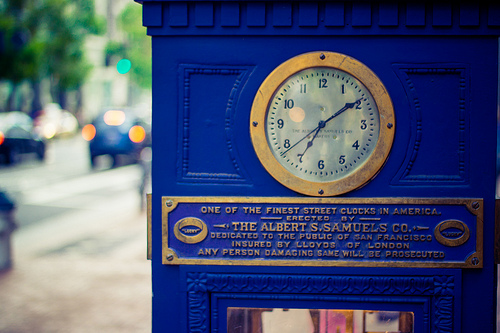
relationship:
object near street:
[148, 4, 495, 331] [3, 132, 150, 332]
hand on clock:
[305, 122, 325, 149] [220, 39, 405, 207]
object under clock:
[135, 0, 500, 333] [245, 49, 398, 197]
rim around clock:
[248, 49, 395, 199] [220, 39, 405, 207]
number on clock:
[339, 79, 348, 97] [245, 49, 398, 197]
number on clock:
[345, 135, 360, 149] [245, 49, 398, 197]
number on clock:
[335, 149, 350, 169] [239, 46, 396, 217]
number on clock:
[314, 158, 326, 170] [245, 49, 398, 197]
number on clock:
[296, 152, 306, 162] [245, 49, 398, 197]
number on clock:
[273, 114, 287, 135] [243, 35, 407, 201]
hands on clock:
[272, 95, 360, 161] [245, 49, 398, 197]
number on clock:
[314, 75, 331, 90] [245, 49, 398, 197]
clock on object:
[131, 1, 498, 331] [135, 0, 500, 333]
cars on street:
[3, 103, 159, 270] [3, 132, 150, 260]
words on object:
[198, 205, 446, 259] [135, 0, 500, 333]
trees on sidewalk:
[3, 4, 150, 104] [0, 112, 102, 152]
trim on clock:
[247, 45, 400, 196] [247, 38, 413, 196]